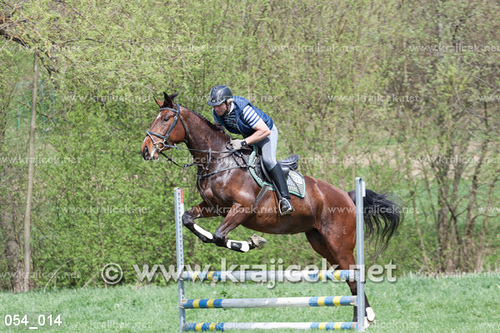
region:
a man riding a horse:
[113, 75, 330, 266]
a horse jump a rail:
[114, 96, 416, 316]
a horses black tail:
[328, 178, 425, 263]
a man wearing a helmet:
[213, 74, 235, 116]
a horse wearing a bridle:
[123, 82, 192, 188]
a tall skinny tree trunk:
[1, 52, 48, 300]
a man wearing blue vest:
[189, 92, 288, 151]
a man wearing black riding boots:
[220, 102, 291, 216]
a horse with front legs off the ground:
[120, 83, 305, 283]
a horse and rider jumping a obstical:
[116, 72, 416, 285]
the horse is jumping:
[135, 78, 414, 323]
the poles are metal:
[167, 203, 396, 331]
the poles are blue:
[178, 296, 358, 331]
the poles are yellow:
[185, 297, 367, 332]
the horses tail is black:
[351, 183, 408, 240]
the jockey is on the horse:
[204, 70, 296, 164]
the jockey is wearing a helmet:
[205, 74, 235, 111]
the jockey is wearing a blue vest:
[234, 95, 273, 141]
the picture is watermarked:
[90, 245, 424, 295]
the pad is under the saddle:
[293, 167, 309, 197]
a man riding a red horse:
[137, 85, 377, 332]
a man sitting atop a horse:
[210, 85, 288, 212]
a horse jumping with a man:
[138, 92, 403, 332]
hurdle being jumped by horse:
[172, 186, 364, 331]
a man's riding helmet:
[208, 85, 235, 105]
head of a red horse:
[138, 93, 232, 161]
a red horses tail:
[351, 185, 403, 246]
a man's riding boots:
[265, 162, 293, 216]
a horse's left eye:
[154, 112, 172, 126]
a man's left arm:
[227, 106, 271, 151]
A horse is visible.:
[140, 118, 261, 263]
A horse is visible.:
[152, 127, 324, 319]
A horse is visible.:
[182, 52, 414, 316]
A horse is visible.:
[257, 164, 459, 319]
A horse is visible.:
[91, 25, 345, 309]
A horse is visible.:
[252, 221, 342, 298]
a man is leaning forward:
[203, 85, 295, 216]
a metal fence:
[167, 177, 377, 327]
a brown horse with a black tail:
[133, 91, 400, 326]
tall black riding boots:
[267, 162, 294, 216]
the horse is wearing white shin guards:
[188, 220, 254, 257]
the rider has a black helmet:
[205, 84, 232, 109]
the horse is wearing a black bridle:
[143, 100, 214, 169]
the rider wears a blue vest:
[208, 95, 278, 136]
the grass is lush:
[2, 270, 494, 331]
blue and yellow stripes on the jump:
[310, 292, 360, 307]